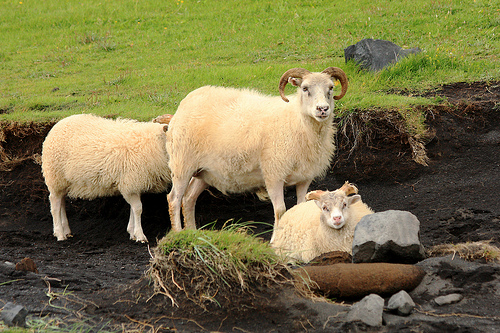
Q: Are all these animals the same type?
A: Yes, all the animals are sheep.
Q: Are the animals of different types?
A: No, all the animals are sheep.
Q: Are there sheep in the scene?
A: Yes, there is a sheep.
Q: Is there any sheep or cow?
A: Yes, there is a sheep.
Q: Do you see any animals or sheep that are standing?
A: Yes, the sheep is standing.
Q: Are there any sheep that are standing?
A: Yes, there is a sheep that is standing.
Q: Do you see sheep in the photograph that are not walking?
A: Yes, there is a sheep that is standing .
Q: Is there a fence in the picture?
A: No, there are no fences.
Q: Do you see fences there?
A: No, there are no fences.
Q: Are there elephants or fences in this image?
A: No, there are no fences or elephants.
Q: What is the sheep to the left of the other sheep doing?
A: The sheep is standing.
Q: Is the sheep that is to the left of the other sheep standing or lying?
A: The sheep is standing.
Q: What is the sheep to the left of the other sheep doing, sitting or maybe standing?
A: The sheep is standing.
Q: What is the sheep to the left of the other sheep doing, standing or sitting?
A: The sheep is standing.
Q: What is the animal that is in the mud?
A: The animal is a sheep.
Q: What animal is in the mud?
A: The animal is a sheep.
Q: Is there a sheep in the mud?
A: Yes, there is a sheep in the mud.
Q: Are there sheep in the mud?
A: Yes, there is a sheep in the mud.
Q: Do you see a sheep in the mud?
A: Yes, there is a sheep in the mud.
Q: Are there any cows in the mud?
A: No, there is a sheep in the mud.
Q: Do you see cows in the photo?
A: No, there are no cows.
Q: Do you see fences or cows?
A: No, there are no cows or fences.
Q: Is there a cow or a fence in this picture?
A: No, there are no cows or fences.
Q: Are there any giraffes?
A: No, there are no giraffes.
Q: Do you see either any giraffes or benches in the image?
A: No, there are no giraffes or benches.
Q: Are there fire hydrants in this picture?
A: No, there are no fire hydrants.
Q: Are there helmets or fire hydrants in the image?
A: No, there are no fire hydrants or helmets.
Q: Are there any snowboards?
A: No, there are no snowboards.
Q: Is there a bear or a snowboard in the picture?
A: No, there are no snowboards or bears.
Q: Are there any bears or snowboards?
A: No, there are no snowboards or bears.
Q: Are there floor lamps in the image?
A: No, there are no floor lamps.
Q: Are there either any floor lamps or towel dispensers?
A: No, there are no floor lamps or towel dispensers.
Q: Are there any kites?
A: No, there are no kites.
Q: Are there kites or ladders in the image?
A: No, there are no kites or ladders.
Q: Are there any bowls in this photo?
A: No, there are no bowls.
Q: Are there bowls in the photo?
A: No, there are no bowls.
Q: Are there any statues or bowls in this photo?
A: No, there are no bowls or statues.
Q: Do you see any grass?
A: Yes, there is grass.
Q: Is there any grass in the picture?
A: Yes, there is grass.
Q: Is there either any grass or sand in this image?
A: Yes, there is grass.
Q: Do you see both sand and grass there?
A: No, there is grass but no sand.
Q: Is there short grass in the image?
A: Yes, there is short grass.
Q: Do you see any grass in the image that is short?
A: Yes, there is grass that is short.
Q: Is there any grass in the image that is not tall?
A: Yes, there is short grass.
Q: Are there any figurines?
A: No, there are no figurines.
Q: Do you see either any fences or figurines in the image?
A: No, there are no figurines or fences.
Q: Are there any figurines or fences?
A: No, there are no figurines or fences.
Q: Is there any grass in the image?
A: Yes, there is grass.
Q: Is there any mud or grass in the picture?
A: Yes, there is grass.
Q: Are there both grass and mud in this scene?
A: Yes, there are both grass and mud.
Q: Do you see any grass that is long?
A: Yes, there is long grass.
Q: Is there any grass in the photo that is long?
A: Yes, there is grass that is long.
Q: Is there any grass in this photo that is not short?
A: Yes, there is long grass.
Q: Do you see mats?
A: No, there are no mats.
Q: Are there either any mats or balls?
A: No, there are no mats or balls.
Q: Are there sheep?
A: Yes, there is a sheep.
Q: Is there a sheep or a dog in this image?
A: Yes, there is a sheep.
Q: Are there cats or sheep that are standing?
A: Yes, the sheep is standing.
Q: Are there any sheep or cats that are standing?
A: Yes, the sheep is standing.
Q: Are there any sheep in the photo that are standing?
A: Yes, there is a sheep that is standing.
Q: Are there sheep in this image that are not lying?
A: Yes, there is a sheep that is standing.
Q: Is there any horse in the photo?
A: No, there are no horses.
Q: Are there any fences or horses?
A: No, there are no horses or fences.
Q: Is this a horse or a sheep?
A: This is a sheep.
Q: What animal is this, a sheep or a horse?
A: This is a sheep.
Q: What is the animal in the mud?
A: The animal is a sheep.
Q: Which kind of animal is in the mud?
A: The animal is a sheep.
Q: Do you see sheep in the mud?
A: Yes, there is a sheep in the mud.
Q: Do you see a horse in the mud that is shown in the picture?
A: No, there is a sheep in the mud.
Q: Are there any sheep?
A: Yes, there is a sheep.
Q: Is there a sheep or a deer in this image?
A: Yes, there is a sheep.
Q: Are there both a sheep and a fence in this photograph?
A: No, there is a sheep but no fences.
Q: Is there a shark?
A: No, there are no sharks.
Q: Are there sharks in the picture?
A: No, there are no sharks.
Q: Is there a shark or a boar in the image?
A: No, there are no sharks or boars.